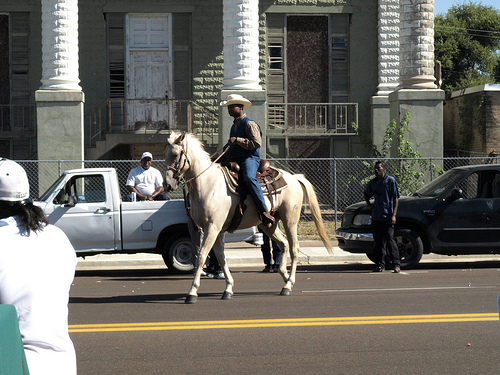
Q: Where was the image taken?
A: It was taken at the street.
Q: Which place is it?
A: It is a street.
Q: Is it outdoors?
A: Yes, it is outdoors.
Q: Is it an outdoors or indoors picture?
A: It is outdoors.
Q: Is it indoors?
A: No, it is outdoors.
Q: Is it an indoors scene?
A: No, it is outdoors.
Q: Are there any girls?
A: No, there are no girls.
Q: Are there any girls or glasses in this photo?
A: No, there are no girls or glasses.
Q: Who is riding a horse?
A: The man is riding a horse.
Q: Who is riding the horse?
A: The man is riding a horse.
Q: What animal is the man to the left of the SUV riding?
A: The man is riding a horse.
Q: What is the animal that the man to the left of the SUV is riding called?
A: The animal is a horse.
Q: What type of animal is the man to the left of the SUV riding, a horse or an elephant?
A: The man is riding a horse.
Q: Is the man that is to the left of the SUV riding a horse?
A: Yes, the man is riding a horse.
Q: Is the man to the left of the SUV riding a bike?
A: No, the man is riding a horse.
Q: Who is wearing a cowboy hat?
A: The man is wearing a cowboy hat.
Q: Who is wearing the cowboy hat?
A: The man is wearing a cowboy hat.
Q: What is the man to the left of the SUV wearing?
A: The man is wearing a cowboy hat.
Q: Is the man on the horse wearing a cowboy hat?
A: Yes, the man is wearing a cowboy hat.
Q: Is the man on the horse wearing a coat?
A: No, the man is wearing a cowboy hat.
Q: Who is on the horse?
A: The man is on the horse.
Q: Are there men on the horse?
A: Yes, there is a man on the horse.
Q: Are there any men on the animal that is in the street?
A: Yes, there is a man on the horse.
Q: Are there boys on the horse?
A: No, there is a man on the horse.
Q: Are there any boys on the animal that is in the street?
A: No, there is a man on the horse.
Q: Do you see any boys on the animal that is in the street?
A: No, there is a man on the horse.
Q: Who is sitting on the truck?
A: The man is sitting on the truck.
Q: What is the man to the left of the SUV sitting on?
A: The man is sitting on the truck.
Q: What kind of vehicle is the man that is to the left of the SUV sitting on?
A: The man is sitting on the truck.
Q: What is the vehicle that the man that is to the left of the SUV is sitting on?
A: The vehicle is a truck.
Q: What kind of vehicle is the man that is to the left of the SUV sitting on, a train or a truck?
A: The man is sitting on a truck.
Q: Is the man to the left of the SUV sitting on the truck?
A: Yes, the man is sitting on the truck.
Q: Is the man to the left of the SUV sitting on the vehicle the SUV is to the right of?
A: Yes, the man is sitting on the truck.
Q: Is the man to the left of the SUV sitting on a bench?
A: No, the man is sitting on the truck.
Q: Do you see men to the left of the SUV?
A: Yes, there is a man to the left of the SUV.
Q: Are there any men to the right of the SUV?
A: No, the man is to the left of the SUV.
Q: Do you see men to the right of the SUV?
A: No, the man is to the left of the SUV.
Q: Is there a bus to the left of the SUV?
A: No, there is a man to the left of the SUV.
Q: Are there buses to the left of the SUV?
A: No, there is a man to the left of the SUV.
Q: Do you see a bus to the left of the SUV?
A: No, there is a man to the left of the SUV.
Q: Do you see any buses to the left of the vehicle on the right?
A: No, there is a man to the left of the SUV.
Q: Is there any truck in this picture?
A: Yes, there is a truck.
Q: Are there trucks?
A: Yes, there is a truck.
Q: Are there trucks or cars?
A: Yes, there is a truck.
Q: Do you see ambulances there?
A: No, there are no ambulances.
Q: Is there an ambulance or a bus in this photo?
A: No, there are no ambulances or buses.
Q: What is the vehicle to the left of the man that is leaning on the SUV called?
A: The vehicle is a truck.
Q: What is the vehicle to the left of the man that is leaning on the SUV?
A: The vehicle is a truck.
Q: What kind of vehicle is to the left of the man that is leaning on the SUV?
A: The vehicle is a truck.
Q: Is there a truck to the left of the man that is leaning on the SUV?
A: Yes, there is a truck to the left of the man.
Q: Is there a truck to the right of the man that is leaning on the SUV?
A: No, the truck is to the left of the man.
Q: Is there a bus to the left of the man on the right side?
A: No, there is a truck to the left of the man.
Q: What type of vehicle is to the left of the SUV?
A: The vehicle is a truck.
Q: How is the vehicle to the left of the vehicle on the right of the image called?
A: The vehicle is a truck.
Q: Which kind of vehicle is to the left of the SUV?
A: The vehicle is a truck.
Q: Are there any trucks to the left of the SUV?
A: Yes, there is a truck to the left of the SUV.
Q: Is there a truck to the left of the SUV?
A: Yes, there is a truck to the left of the SUV.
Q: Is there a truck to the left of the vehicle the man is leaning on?
A: Yes, there is a truck to the left of the SUV.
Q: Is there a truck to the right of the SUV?
A: No, the truck is to the left of the SUV.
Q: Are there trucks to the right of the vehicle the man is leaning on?
A: No, the truck is to the left of the SUV.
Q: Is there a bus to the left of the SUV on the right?
A: No, there is a truck to the left of the SUV.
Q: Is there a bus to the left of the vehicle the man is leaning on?
A: No, there is a truck to the left of the SUV.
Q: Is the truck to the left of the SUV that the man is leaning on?
A: Yes, the truck is to the left of the SUV.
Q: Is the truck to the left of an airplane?
A: No, the truck is to the left of the SUV.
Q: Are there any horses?
A: Yes, there is a horse.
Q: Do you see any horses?
A: Yes, there is a horse.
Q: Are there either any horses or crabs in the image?
A: Yes, there is a horse.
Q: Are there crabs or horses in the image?
A: Yes, there is a horse.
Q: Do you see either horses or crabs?
A: Yes, there is a horse.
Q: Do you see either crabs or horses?
A: Yes, there is a horse.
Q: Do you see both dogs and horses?
A: No, there is a horse but no dogs.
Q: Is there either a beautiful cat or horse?
A: Yes, there is a beautiful horse.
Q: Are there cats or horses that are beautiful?
A: Yes, the horse is beautiful.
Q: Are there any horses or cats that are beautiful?
A: Yes, the horse is beautiful.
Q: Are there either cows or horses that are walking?
A: Yes, the horse is walking.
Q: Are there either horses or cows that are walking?
A: Yes, the horse is walking.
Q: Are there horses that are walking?
A: Yes, there is a horse that is walking.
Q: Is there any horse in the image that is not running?
A: Yes, there is a horse that is walking.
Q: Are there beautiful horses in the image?
A: Yes, there is a beautiful horse.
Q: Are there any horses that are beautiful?
A: Yes, there is a horse that is beautiful.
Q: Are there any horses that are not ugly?
A: Yes, there is an beautiful horse.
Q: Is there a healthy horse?
A: Yes, there is a healthy horse.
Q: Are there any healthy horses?
A: Yes, there is a healthy horse.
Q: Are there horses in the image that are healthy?
A: Yes, there is a horse that is healthy.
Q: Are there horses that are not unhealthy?
A: Yes, there is an healthy horse.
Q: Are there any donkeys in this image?
A: No, there are no donkeys.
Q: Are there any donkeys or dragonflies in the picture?
A: No, there are no donkeys or dragonflies.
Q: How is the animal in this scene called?
A: The animal is a horse.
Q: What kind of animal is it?
A: The animal is a horse.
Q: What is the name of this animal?
A: That is a horse.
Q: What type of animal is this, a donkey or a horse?
A: That is a horse.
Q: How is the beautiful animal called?
A: The animal is a horse.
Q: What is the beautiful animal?
A: The animal is a horse.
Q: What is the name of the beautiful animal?
A: The animal is a horse.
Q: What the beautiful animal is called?
A: The animal is a horse.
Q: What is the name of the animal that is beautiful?
A: The animal is a horse.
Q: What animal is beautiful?
A: The animal is a horse.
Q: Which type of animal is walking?
A: The animal is a horse.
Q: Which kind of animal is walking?
A: The animal is a horse.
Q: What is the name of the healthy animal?
A: The animal is a horse.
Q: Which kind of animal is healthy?
A: The animal is a horse.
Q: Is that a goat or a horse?
A: That is a horse.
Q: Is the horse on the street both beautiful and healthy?
A: Yes, the horse is beautiful and healthy.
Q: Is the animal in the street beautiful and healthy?
A: Yes, the horse is beautiful and healthy.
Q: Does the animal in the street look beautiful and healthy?
A: Yes, the horse is beautiful and healthy.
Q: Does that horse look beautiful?
A: Yes, the horse is beautiful.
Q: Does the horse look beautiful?
A: Yes, the horse is beautiful.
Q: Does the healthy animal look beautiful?
A: Yes, the horse is beautiful.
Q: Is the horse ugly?
A: No, the horse is beautiful.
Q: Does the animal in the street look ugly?
A: No, the horse is beautiful.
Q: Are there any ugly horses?
A: No, there is a horse but it is beautiful.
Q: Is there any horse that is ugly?
A: No, there is a horse but it is beautiful.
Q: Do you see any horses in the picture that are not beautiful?
A: No, there is a horse but it is beautiful.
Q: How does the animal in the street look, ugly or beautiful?
A: The horse is beautiful.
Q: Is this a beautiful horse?
A: Yes, this is a beautiful horse.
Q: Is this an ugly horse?
A: No, this is a beautiful horse.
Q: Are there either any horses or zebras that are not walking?
A: No, there is a horse but it is walking.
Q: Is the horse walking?
A: Yes, the horse is walking.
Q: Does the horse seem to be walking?
A: Yes, the horse is walking.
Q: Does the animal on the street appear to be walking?
A: Yes, the horse is walking.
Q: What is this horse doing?
A: The horse is walking.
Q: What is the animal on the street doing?
A: The horse is walking.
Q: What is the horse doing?
A: The horse is walking.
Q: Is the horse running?
A: No, the horse is walking.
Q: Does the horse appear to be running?
A: No, the horse is walking.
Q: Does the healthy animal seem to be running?
A: No, the horse is walking.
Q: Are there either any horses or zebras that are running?
A: No, there is a horse but it is walking.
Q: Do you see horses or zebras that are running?
A: No, there is a horse but it is walking.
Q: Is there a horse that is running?
A: No, there is a horse but it is walking.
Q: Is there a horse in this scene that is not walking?
A: No, there is a horse but it is walking.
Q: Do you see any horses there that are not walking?
A: No, there is a horse but it is walking.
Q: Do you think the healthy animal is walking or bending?
A: The horse is walking.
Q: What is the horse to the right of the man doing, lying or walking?
A: The horse is walking.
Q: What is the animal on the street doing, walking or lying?
A: The horse is walking.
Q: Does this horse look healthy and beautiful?
A: Yes, the horse is healthy and beautiful.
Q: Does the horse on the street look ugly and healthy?
A: No, the horse is healthy but beautiful.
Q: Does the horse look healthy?
A: Yes, the horse is healthy.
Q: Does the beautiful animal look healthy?
A: Yes, the horse is healthy.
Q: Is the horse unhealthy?
A: No, the horse is healthy.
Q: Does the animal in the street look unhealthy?
A: No, the horse is healthy.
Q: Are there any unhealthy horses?
A: No, there is a horse but it is healthy.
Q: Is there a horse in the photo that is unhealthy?
A: No, there is a horse but it is healthy.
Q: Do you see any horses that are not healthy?
A: No, there is a horse but it is healthy.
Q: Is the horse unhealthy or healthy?
A: The horse is healthy.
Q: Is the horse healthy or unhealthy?
A: The horse is healthy.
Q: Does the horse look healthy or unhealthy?
A: The horse is healthy.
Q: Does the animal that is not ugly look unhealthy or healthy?
A: The horse is healthy.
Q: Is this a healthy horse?
A: Yes, this is a healthy horse.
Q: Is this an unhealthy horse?
A: No, this is a healthy horse.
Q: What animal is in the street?
A: The horse is in the street.